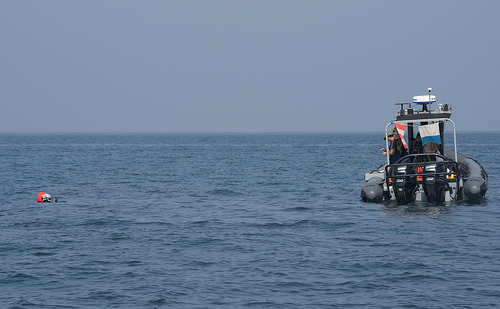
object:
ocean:
[1, 132, 498, 308]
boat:
[360, 88, 488, 203]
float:
[37, 192, 58, 203]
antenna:
[428, 88, 433, 114]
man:
[380, 132, 400, 164]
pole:
[385, 118, 458, 165]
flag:
[393, 121, 408, 151]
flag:
[418, 123, 442, 148]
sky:
[1, 0, 499, 131]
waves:
[247, 218, 445, 228]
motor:
[391, 162, 448, 204]